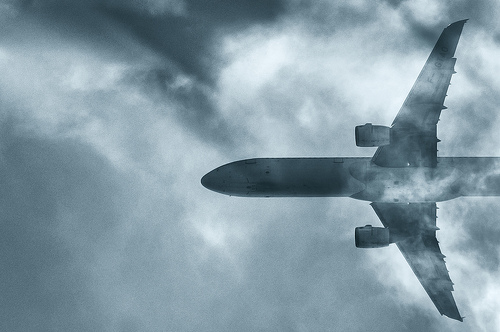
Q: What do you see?
A: A jet.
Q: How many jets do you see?
A: One.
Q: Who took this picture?
A: A photographer.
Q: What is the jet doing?
A: Flying.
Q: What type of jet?
A: Boeing.